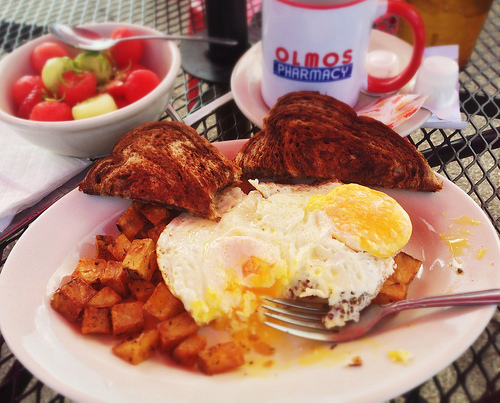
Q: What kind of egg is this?
A: Sunny side up.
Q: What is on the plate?
A: Potatoes.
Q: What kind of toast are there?
A: Crispy.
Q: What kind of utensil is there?
A: Fork.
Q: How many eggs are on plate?
A: Two.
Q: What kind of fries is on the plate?
A: Home fries.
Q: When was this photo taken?
A: During a mealtime.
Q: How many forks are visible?
A: One.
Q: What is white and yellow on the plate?
A: Eggs.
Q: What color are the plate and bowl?
A: White.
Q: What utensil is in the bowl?
A: A spoon.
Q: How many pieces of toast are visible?
A: Two.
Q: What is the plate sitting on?
A: A grated table.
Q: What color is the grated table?
A: Black.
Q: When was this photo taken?
A: Outside, during the daytime.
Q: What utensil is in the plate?
A: Fork.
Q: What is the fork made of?
A: Metal.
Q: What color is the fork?
A: Silver.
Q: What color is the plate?
A: White.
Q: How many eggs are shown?
A: 2.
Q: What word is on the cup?
A: OLMOS Pharmacy.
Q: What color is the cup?
A: Red, white, and blue.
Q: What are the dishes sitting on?
A: Table.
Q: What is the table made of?
A: Metal.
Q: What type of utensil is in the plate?
A: Fork.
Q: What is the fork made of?
A: Metal.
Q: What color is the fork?
A: Silver.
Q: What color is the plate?
A: White.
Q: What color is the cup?
A: Red, white, and blue.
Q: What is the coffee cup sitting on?
A: Saucer.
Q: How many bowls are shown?
A: 1.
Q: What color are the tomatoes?
A: Red.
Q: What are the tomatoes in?
A: Bowl.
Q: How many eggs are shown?
A: 2.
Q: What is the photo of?
A: Breakfast.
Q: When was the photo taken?
A: Daytime.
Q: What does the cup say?
A: Olmos pharmacy.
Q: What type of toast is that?
A: Rye.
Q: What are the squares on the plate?
A: Potatoes.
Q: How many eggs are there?
A: 2.